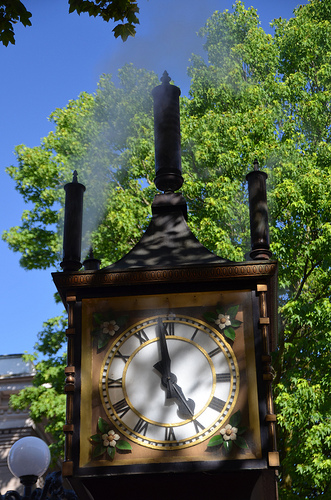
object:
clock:
[78, 288, 264, 468]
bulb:
[5, 435, 52, 483]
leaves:
[201, 76, 268, 116]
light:
[0, 428, 19, 462]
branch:
[292, 254, 321, 302]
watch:
[98, 313, 242, 452]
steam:
[103, 74, 106, 228]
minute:
[151, 358, 198, 419]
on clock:
[78, 288, 262, 468]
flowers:
[212, 309, 234, 330]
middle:
[152, 400, 184, 450]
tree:
[7, 0, 330, 500]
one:
[190, 322, 200, 342]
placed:
[81, 214, 250, 275]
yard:
[290, 485, 317, 499]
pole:
[150, 82, 184, 193]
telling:
[149, 328, 218, 427]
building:
[0, 352, 75, 500]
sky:
[0, 0, 331, 368]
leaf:
[224, 325, 236, 343]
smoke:
[53, 0, 249, 277]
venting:
[59, 191, 108, 270]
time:
[134, 326, 150, 346]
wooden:
[49, 66, 282, 498]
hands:
[155, 315, 178, 401]